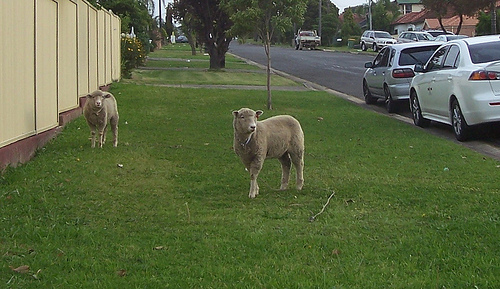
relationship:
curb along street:
[295, 76, 307, 87] [229, 39, 499, 156]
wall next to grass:
[0, 1, 122, 176] [2, 42, 500, 287]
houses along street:
[340, 1, 499, 47] [229, 39, 499, 156]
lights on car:
[470, 68, 496, 85] [407, 31, 497, 143]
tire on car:
[412, 90, 430, 128] [407, 31, 497, 143]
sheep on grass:
[81, 90, 120, 149] [2, 42, 500, 287]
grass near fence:
[2, 42, 500, 287] [1, 1, 122, 175]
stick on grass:
[311, 186, 340, 223] [2, 42, 500, 287]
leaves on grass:
[78, 155, 127, 176] [2, 42, 500, 287]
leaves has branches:
[236, 13, 255, 25] [233, 5, 271, 41]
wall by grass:
[0, 1, 122, 176] [2, 42, 500, 287]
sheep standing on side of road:
[81, 87, 121, 150] [227, 35, 484, 148]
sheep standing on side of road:
[229, 104, 308, 197] [227, 35, 484, 148]